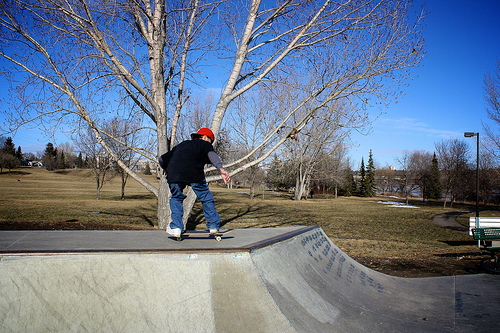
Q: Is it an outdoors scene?
A: Yes, it is outdoors.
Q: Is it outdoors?
A: Yes, it is outdoors.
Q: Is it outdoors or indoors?
A: It is outdoors.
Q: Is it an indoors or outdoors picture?
A: It is outdoors.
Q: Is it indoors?
A: No, it is outdoors.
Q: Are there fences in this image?
A: No, there are no fences.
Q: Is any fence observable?
A: No, there are no fences.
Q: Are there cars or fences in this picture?
A: No, there are no fences or cars.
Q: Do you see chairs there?
A: No, there are no chairs.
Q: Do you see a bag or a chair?
A: No, there are no chairs or bags.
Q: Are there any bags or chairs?
A: No, there are no chairs or bags.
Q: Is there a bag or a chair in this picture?
A: No, there are no chairs or bags.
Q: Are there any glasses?
A: No, there are no glasses.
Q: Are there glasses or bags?
A: No, there are no glasses or bags.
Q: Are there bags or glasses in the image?
A: No, there are no glasses or bags.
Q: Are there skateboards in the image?
A: Yes, there is a skateboard.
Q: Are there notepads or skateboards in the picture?
A: Yes, there is a skateboard.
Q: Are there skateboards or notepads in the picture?
A: Yes, there is a skateboard.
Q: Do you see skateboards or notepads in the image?
A: Yes, there is a skateboard.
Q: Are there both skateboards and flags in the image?
A: No, there is a skateboard but no flags.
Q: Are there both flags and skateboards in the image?
A: No, there is a skateboard but no flags.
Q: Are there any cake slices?
A: No, there are no cake slices.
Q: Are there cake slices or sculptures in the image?
A: No, there are no cake slices or sculptures.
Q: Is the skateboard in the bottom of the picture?
A: Yes, the skateboard is in the bottom of the image.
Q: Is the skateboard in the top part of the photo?
A: No, the skateboard is in the bottom of the image.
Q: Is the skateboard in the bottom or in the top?
A: The skateboard is in the bottom of the image.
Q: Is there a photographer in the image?
A: No, there are no photographers.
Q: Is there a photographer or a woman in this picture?
A: No, there are no photographers or women.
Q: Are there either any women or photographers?
A: No, there are no photographers or women.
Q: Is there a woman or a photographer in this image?
A: No, there are no photographers or women.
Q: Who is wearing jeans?
A: The boy is wearing jeans.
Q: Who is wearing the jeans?
A: The boy is wearing jeans.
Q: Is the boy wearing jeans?
A: Yes, the boy is wearing jeans.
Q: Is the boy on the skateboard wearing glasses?
A: No, the boy is wearing jeans.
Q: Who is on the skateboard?
A: The boy is on the skateboard.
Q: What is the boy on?
A: The boy is on the skateboard.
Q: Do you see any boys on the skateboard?
A: Yes, there is a boy on the skateboard.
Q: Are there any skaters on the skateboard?
A: No, there is a boy on the skateboard.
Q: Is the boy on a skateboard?
A: Yes, the boy is on a skateboard.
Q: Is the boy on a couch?
A: No, the boy is on a skateboard.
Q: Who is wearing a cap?
A: The boy is wearing a cap.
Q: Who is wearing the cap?
A: The boy is wearing a cap.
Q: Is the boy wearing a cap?
A: Yes, the boy is wearing a cap.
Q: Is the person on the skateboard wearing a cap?
A: Yes, the boy is wearing a cap.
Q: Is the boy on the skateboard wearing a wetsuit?
A: No, the boy is wearing a cap.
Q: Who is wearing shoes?
A: The boy is wearing shoes.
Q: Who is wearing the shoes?
A: The boy is wearing shoes.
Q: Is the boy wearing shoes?
A: Yes, the boy is wearing shoes.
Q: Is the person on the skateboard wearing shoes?
A: Yes, the boy is wearing shoes.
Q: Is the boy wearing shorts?
A: No, the boy is wearing shoes.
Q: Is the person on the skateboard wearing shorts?
A: No, the boy is wearing shoes.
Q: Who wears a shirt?
A: The boy wears a shirt.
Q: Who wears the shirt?
A: The boy wears a shirt.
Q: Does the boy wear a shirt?
A: Yes, the boy wears a shirt.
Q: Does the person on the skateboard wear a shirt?
A: Yes, the boy wears a shirt.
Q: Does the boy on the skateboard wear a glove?
A: No, the boy wears a shirt.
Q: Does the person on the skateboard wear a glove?
A: No, the boy wears a shirt.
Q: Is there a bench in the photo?
A: Yes, there is a bench.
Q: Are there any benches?
A: Yes, there is a bench.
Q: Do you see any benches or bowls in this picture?
A: Yes, there is a bench.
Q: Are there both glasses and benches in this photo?
A: No, there is a bench but no glasses.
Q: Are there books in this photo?
A: No, there are no books.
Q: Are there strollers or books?
A: No, there are no books or strollers.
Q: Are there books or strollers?
A: No, there are no books or strollers.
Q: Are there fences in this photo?
A: No, there are no fences.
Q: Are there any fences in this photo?
A: No, there are no fences.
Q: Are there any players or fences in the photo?
A: No, there are no fences or players.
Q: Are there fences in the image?
A: No, there are no fences.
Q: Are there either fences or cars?
A: No, there are no fences or cars.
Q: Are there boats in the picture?
A: No, there are no boats.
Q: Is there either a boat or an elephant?
A: No, there are no boats or elephants.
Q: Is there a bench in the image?
A: Yes, there is a bench.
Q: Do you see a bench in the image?
A: Yes, there is a bench.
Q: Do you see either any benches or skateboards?
A: Yes, there is a bench.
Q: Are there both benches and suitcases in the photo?
A: No, there is a bench but no suitcases.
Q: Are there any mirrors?
A: No, there are no mirrors.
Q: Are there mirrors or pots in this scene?
A: No, there are no mirrors or pots.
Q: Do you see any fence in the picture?
A: No, there are no fences.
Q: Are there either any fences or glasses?
A: No, there are no fences or glasses.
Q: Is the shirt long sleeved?
A: Yes, the shirt is long sleeved.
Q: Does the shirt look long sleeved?
A: Yes, the shirt is long sleeved.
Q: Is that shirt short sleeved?
A: No, the shirt is long sleeved.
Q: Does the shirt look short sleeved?
A: No, the shirt is long sleeved.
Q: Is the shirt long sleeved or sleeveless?
A: The shirt is long sleeved.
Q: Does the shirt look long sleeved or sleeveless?
A: The shirt is long sleeved.